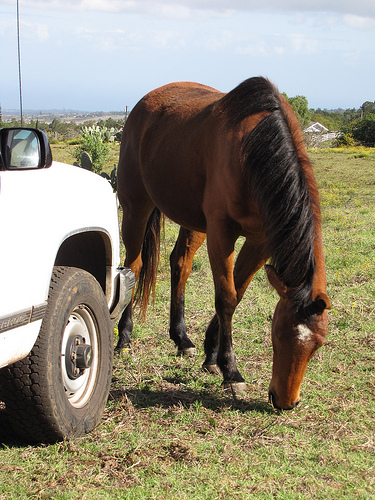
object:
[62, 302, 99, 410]
rim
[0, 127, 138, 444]
truck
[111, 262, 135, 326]
bumper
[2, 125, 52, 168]
mirror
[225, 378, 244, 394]
hooves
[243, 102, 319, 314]
mane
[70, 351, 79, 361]
nut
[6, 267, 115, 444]
tire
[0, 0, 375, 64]
cloud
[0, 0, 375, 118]
sky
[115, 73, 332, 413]
horse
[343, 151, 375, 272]
grass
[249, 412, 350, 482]
grass